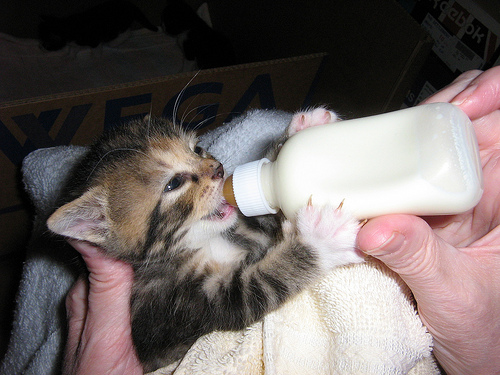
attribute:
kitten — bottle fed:
[42, 110, 360, 371]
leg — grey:
[209, 247, 320, 327]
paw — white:
[272, 191, 382, 274]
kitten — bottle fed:
[22, 137, 341, 374]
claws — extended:
[285, 193, 349, 223]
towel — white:
[43, 98, 440, 372]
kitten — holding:
[28, 82, 310, 372]